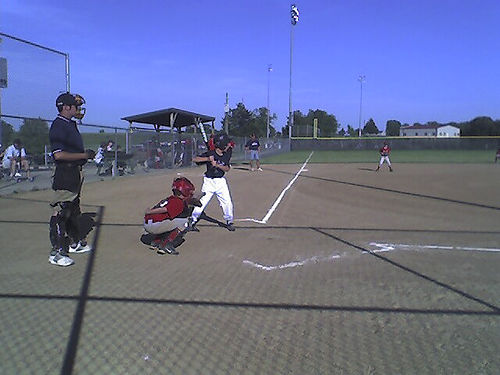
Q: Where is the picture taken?
A: Baseball field.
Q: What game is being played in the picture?
A: Baseball.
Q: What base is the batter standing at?
A: Home base.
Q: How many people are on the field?
A: 5.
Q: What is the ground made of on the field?
A: Dirt.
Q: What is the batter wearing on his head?
A: A helmet.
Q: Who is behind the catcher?
A: The umpire.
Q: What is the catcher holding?
A: Mit.